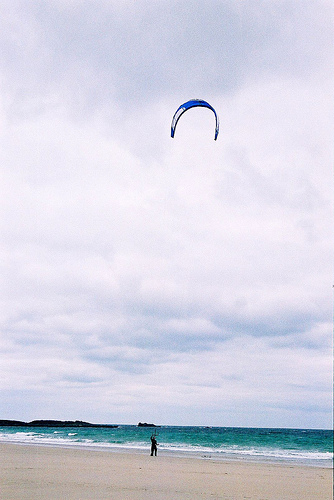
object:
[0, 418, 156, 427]
mountains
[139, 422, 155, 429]
background land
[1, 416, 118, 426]
background land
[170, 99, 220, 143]
object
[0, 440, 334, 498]
sand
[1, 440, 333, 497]
land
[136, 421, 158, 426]
rock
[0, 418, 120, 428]
rock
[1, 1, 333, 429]
cloudy sky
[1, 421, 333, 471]
water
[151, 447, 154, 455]
legs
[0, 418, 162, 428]
jetty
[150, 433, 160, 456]
man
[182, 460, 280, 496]
pole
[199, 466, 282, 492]
ball player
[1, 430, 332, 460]
wave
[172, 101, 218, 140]
boomerang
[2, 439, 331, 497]
shore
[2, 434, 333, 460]
spray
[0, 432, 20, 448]
end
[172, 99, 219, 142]
kite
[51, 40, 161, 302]
air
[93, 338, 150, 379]
cloud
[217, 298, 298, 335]
cloud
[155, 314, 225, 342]
cloud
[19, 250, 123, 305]
cloud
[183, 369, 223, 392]
cloud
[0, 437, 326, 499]
beach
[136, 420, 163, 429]
protrusion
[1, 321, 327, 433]
background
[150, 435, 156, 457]
clothing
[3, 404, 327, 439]
skyline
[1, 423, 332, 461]
ocean